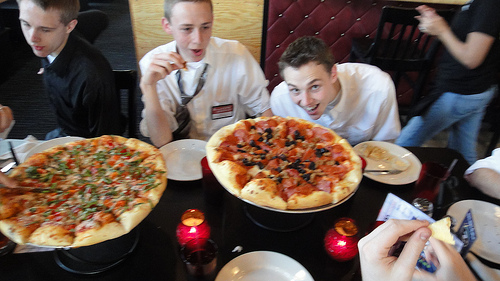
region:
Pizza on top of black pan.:
[195, 103, 372, 220]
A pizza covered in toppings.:
[0, 122, 185, 259]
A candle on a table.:
[323, 219, 364, 261]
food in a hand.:
[423, 207, 463, 254]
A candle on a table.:
[169, 204, 213, 248]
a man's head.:
[6, 0, 76, 65]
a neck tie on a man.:
[167, 42, 218, 140]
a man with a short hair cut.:
[267, 32, 350, 132]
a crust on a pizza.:
[65, 206, 132, 252]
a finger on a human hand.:
[391, 222, 438, 277]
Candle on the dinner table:
[175, 206, 212, 250]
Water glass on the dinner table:
[180, 237, 217, 277]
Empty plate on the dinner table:
[213, 248, 316, 279]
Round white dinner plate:
[155, 137, 211, 179]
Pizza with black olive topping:
[206, 114, 363, 212]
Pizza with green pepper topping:
[1, 133, 166, 249]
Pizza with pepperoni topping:
[207, 115, 364, 215]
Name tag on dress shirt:
[210, 101, 234, 121]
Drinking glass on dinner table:
[416, 151, 457, 202]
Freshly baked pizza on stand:
[203, 114, 363, 214]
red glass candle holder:
[176, 207, 211, 250]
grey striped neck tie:
[170, 59, 209, 139]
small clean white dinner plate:
[157, 137, 212, 181]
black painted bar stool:
[347, 2, 439, 124]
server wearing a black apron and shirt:
[393, 0, 498, 167]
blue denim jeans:
[389, 85, 499, 165]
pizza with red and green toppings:
[0, 133, 167, 247]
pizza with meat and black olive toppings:
[202, 113, 363, 208]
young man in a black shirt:
[14, 1, 126, 137]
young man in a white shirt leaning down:
[268, 32, 401, 147]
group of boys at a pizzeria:
[0, 0, 402, 146]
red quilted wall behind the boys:
[262, 2, 449, 126]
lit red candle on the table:
[173, 207, 211, 245]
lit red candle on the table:
[322, 218, 362, 259]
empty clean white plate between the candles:
[215, 248, 314, 279]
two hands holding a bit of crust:
[356, 215, 472, 279]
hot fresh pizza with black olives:
[205, 116, 367, 213]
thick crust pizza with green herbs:
[0, 132, 166, 245]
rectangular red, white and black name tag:
[207, 102, 241, 121]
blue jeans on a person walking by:
[397, 91, 499, 162]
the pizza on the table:
[212, 113, 363, 207]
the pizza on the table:
[12, 134, 160, 248]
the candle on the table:
[169, 203, 215, 244]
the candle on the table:
[320, 218, 365, 260]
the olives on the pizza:
[285, 129, 310, 155]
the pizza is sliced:
[0, 142, 167, 240]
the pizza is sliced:
[207, 117, 360, 211]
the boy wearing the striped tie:
[170, 73, 216, 137]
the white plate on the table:
[210, 250, 323, 275]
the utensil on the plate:
[364, 160, 407, 180]